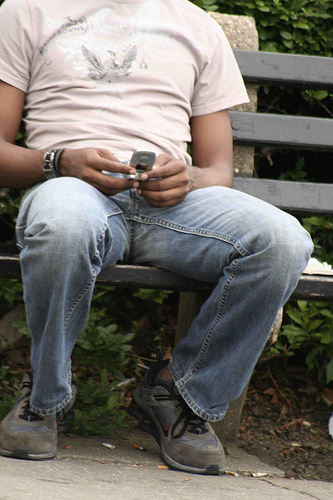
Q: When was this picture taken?
A: During daylight.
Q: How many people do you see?
A: 1.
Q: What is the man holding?
A: A cell phone.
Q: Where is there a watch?
A: The man's right wrist.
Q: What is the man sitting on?
A: A bench.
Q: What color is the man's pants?
A: Blue.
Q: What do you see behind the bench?
A: Bushes.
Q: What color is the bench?
A: Gray.